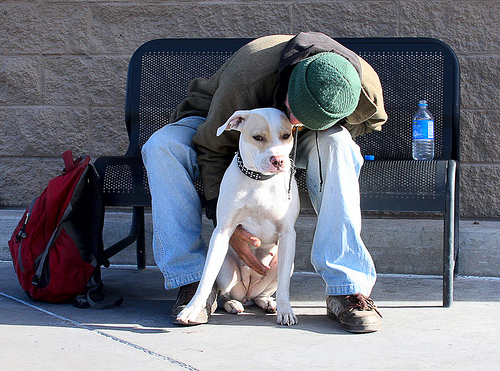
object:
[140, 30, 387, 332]
man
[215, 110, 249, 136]
ears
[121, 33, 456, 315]
man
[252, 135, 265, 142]
eye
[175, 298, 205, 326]
paw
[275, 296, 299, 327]
paw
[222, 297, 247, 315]
paw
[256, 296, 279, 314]
paw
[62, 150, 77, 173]
handle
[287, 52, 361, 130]
hat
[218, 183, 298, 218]
chest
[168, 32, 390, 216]
hoodie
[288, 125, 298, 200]
draw stings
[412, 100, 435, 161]
bottle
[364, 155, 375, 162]
blue cap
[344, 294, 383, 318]
brown laces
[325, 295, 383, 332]
shoe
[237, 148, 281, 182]
black collar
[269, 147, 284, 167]
nose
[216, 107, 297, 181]
head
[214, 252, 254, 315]
hind legs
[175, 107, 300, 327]
dog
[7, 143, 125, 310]
backpack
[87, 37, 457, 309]
bench